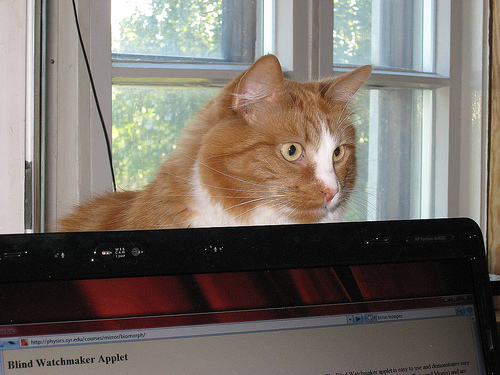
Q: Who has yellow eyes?
A: The orange tabby.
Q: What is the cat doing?
A: Looking over the laptop.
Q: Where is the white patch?
A: On the cat's nose.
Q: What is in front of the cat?
A: Laptop.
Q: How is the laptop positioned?
A: Open.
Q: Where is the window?
A: Behind the cat.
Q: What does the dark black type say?
A: Blind Watchmaker Applet.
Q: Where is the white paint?
A: On the window.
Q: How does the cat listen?
A: Ears.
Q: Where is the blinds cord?
A: Behind the cat.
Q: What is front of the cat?
A: Part of a laptop.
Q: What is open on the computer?
A: A webpage.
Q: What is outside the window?
A: Trees.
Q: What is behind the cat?
A: A white window.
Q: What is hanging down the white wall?
A: A black cord.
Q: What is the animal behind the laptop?
A: A tan and white cat.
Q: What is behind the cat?
A: A lower right window pane.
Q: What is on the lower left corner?
A: A window pane.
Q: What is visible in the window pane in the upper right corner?
A: A tree.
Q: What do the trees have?
A: Green leaves.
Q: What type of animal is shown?
A: A cat.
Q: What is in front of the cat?
A: A computer.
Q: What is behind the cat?
A: A window.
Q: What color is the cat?
A: Orange and white.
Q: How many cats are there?
A: One.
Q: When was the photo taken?
A: Daytime.